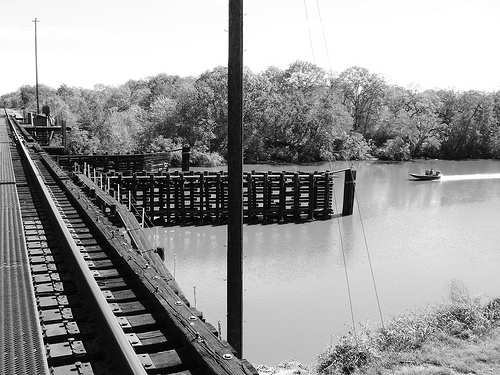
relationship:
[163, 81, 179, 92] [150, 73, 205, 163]
leaf growing on plant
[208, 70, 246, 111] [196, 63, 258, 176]
leaf growing on plant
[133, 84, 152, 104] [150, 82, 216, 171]
leaf growing on plant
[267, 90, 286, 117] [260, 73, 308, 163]
leaf growing on plant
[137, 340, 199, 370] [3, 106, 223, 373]
board attached to bridge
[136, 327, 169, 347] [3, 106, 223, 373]
board attached to bridge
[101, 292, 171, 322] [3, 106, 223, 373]
board attached to bridge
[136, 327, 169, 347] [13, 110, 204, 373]
board attached to bridge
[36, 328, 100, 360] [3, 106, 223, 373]
board attached to bridge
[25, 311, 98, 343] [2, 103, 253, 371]
board attached to bridge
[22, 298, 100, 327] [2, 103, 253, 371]
board attached to bridge